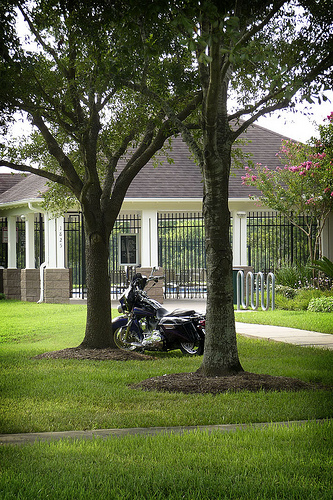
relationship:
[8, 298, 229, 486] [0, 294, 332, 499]
grass on ground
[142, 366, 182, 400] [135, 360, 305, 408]
paper on mound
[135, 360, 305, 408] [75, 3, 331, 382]
mound around tree trunk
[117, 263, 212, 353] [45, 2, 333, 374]
motorcycle under tree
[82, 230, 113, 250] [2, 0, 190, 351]
cross on tree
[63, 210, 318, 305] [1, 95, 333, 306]
bars are by building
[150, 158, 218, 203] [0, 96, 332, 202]
shingles are on roof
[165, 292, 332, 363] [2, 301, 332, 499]
concrete between grass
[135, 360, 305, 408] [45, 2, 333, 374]
mound under tree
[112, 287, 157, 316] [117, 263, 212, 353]
motor on motorcycle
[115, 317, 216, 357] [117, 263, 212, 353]
tires are on motorcycle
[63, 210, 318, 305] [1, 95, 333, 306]
bars are on building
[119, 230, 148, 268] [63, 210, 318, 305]
plaque on bars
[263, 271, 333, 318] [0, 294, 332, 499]
plants are on ground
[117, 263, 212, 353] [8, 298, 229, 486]
motorcycle in grass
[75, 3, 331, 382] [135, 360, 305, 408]
tree trunk in mound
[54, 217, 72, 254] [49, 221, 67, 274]
numbers are on beam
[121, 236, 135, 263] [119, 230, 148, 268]
plaque on plaque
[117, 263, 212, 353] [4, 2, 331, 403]
motorcycle by trees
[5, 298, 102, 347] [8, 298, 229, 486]
sun on grass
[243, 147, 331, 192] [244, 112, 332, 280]
flowers are on tree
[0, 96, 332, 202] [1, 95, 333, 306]
roof on building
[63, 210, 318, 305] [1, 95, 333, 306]
bars are in front of building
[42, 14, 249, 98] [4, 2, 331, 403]
leaves are on trees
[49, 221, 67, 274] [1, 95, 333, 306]
beam on building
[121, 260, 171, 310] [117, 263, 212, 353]
handlebars are on motorcycle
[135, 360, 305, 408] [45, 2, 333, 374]
mound around tree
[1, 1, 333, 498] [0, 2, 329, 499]
photo was taken in daytime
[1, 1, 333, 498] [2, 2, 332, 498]
photo was taken outdoors